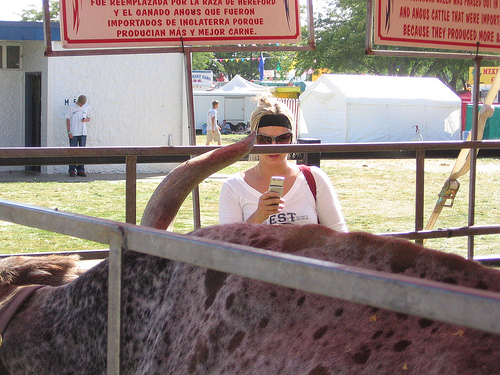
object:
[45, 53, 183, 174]
wall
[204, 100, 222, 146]
boy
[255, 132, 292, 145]
sunglasses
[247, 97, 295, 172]
hair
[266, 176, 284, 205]
phone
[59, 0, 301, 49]
sign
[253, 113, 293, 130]
headband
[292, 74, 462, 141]
tent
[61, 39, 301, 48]
border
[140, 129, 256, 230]
horn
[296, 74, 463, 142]
tarp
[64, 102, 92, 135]
shirt